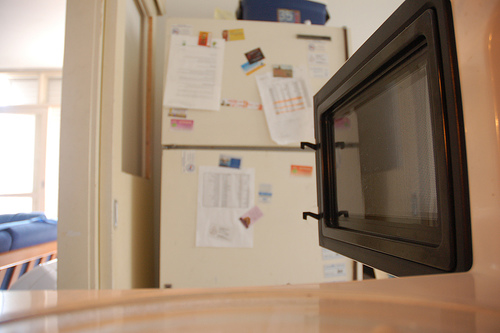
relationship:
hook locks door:
[297, 137, 319, 156] [295, 2, 476, 283]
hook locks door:
[300, 207, 325, 226] [295, 2, 476, 283]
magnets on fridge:
[270, 60, 293, 81] [156, 13, 367, 291]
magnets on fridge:
[222, 26, 247, 45] [156, 13, 367, 291]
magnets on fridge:
[196, 28, 222, 51] [156, 13, 367, 291]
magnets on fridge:
[244, 44, 267, 67] [156, 13, 367, 291]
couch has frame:
[1, 209, 61, 295] [1, 238, 61, 293]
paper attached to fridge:
[162, 33, 230, 117] [156, 13, 367, 291]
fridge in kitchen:
[156, 13, 367, 291] [0, 1, 498, 332]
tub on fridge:
[235, 1, 335, 30] [156, 13, 367, 291]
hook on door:
[297, 137, 319, 156] [295, 2, 476, 283]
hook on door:
[300, 207, 325, 226] [295, 2, 476, 283]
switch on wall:
[112, 199, 122, 227] [96, 1, 167, 292]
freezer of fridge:
[155, 13, 365, 155] [156, 13, 367, 291]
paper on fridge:
[162, 33, 230, 117] [156, 13, 367, 291]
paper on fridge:
[193, 160, 259, 255] [156, 13, 367, 291]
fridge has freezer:
[156, 13, 367, 291] [155, 13, 365, 155]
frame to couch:
[1, 238, 61, 293] [1, 209, 61, 295]